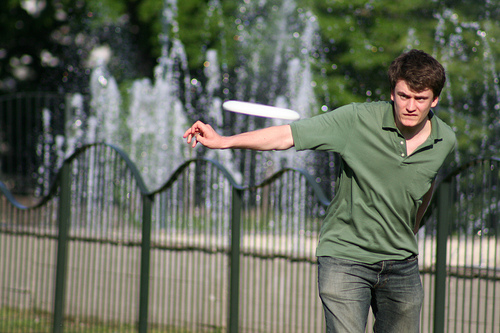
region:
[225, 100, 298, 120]
white Frisbee flying through the air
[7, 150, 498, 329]
a green fence with a curved top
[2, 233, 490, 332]
the street behind the fence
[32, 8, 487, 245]
a fountain on the other side of the street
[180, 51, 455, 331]
man with a green shirt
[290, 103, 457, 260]
the man's green polo shirt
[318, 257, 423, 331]
faded blue jeans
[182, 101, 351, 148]
the man's right arm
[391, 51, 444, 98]
brown hair on the man's head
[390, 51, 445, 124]
the man's head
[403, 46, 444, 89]
hair of the man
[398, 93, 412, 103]
eye of the man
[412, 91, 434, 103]
eye of the man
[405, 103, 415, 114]
nose of the man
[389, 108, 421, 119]
mouth of the man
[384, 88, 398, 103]
ear of the man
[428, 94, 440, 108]
ear of the man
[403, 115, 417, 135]
chin of the man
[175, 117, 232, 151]
hand of the man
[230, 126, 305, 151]
arm of the man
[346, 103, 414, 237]
A green shirt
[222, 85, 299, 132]
A frisbee in the air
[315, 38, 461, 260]
A man in the photo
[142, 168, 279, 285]
A fence in the photo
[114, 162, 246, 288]
Metal bars in the background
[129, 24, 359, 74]
Trees growing in the photo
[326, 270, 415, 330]
Jeans in the photo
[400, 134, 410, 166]
Buttons on the shirt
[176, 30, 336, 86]
Water in the background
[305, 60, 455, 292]
A man playing frisbee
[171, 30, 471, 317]
Man is playing frisbee.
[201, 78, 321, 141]
frisbee is white in color.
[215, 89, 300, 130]
Frisbee is white color.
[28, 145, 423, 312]
Fence is green color.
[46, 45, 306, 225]
Fountain is behind the fence.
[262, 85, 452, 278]
Man is wearing green shirt.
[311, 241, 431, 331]
Man is wearing grey pant.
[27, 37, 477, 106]
Trees are behind the fountain.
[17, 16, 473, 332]
Day time picture.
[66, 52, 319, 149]
water is white color in fountain.